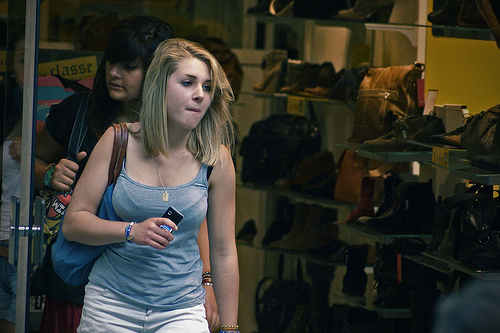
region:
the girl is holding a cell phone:
[67, 183, 186, 260]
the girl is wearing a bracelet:
[95, 212, 140, 249]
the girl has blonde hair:
[95, 24, 239, 157]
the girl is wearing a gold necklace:
[118, 122, 200, 218]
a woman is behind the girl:
[27, 0, 237, 251]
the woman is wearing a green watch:
[23, 143, 63, 200]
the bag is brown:
[324, 36, 434, 116]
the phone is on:
[99, 182, 186, 262]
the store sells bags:
[119, 7, 471, 299]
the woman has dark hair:
[73, 9, 236, 116]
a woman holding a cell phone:
[67, 49, 289, 325]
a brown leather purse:
[366, 51, 449, 121]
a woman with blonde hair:
[144, 23, 244, 160]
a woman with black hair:
[90, 22, 159, 105]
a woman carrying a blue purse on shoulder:
[47, 40, 249, 290]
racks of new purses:
[236, 37, 381, 331]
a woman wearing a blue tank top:
[45, 47, 262, 327]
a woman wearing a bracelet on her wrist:
[97, 24, 247, 281]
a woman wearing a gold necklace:
[102, 42, 252, 228]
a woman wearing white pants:
[131, 45, 236, 329]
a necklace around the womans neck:
[140, 127, 193, 202]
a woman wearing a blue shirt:
[62, 19, 239, 328]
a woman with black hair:
[29, 12, 166, 250]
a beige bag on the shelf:
[356, 54, 428, 157]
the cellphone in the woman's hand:
[147, 205, 182, 241]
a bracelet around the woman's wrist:
[123, 220, 135, 247]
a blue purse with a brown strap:
[50, 101, 129, 293]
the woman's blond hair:
[140, 40, 232, 161]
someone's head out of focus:
[436, 260, 498, 330]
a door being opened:
[14, 2, 146, 332]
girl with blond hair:
[120, 35, 240, 166]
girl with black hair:
[93, 13, 175, 101]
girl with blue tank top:
[88, 50, 211, 307]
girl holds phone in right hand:
[160, 196, 187, 247]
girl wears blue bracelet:
[122, 220, 137, 246]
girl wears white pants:
[77, 280, 214, 330]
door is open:
[0, 0, 36, 330]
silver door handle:
[1, 190, 46, 265]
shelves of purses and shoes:
[236, 0, 491, 330]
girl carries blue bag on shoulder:
[47, 122, 125, 285]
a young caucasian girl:
[62, 37, 240, 331]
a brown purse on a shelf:
[348, 58, 429, 139]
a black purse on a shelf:
[446, 182, 495, 273]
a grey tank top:
[87, 153, 213, 309]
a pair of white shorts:
[73, 282, 212, 331]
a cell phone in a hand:
[153, 205, 189, 242]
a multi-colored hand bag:
[32, 178, 68, 271]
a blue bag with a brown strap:
[48, 119, 130, 284]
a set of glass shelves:
[234, 5, 499, 331]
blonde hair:
[133, 39, 237, 175]